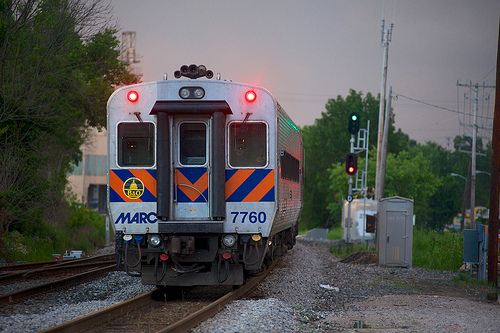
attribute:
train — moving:
[104, 76, 286, 272]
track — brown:
[122, 293, 196, 332]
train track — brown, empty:
[65, 294, 235, 333]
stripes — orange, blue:
[174, 169, 282, 205]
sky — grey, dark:
[251, 8, 500, 89]